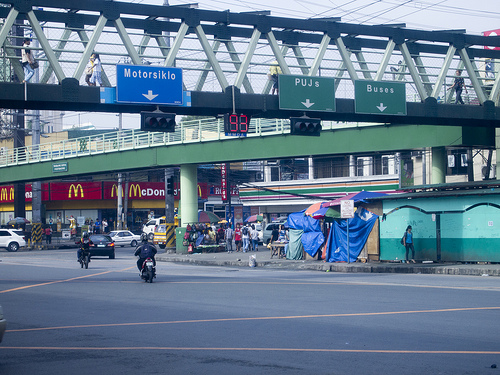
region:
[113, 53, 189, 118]
sign above the street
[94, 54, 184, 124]
blue and white sign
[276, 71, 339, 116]
green and white sign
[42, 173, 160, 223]
restaurant next to street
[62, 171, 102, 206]
yellow m on building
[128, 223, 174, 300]
person on a bike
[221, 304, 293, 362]
line on the street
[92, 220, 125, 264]
cars on the road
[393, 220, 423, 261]
person walking on cement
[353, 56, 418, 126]
sign for the buses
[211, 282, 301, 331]
a street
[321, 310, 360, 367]
a street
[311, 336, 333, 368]
a street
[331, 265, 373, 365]
a street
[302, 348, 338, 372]
a street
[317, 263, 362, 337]
a street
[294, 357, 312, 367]
a street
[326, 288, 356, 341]
a street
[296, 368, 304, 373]
a street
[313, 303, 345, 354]
a street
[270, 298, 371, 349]
A yellow line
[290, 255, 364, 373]
A yellow line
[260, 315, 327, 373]
A yellow line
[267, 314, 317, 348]
A yellow line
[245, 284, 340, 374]
A yellow line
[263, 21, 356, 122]
A green sign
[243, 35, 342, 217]
A green sign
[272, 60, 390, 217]
A green sign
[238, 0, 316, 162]
A green sign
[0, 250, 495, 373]
black asphalt street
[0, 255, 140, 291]
yellow painted line on street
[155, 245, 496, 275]
gray concrete sidewalk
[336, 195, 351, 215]
white and red sign on pole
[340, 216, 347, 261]
metal pole on sidewalk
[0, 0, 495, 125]
pedestrian walkway over street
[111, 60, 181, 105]
blue and white street sign on walkway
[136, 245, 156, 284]
dark colored motorcycle on street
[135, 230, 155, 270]
person riding motorcycle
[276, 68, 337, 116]
green and white traffic sign